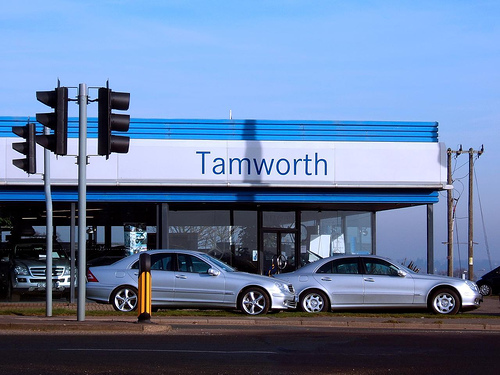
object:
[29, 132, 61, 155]
street lights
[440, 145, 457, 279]
powerlines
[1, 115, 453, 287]
dealership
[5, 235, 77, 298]
suv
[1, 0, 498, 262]
sky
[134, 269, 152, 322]
reflector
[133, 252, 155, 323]
post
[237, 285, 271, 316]
wheel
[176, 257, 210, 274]
window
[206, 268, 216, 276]
side mirror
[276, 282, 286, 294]
headlight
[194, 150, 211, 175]
letters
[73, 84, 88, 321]
pole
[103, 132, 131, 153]
light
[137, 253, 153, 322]
sign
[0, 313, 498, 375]
road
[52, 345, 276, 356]
lines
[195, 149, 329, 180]
logo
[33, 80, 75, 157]
traffic lights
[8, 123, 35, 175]
traffic light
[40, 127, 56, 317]
pole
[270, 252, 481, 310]
car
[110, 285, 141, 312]
tire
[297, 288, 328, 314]
tire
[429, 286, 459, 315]
tire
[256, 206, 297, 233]
window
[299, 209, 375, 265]
window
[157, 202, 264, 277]
frame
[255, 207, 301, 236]
frame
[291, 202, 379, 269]
frame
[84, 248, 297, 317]
car